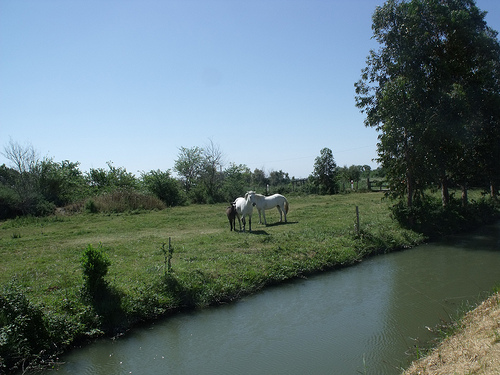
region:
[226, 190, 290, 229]
three horses standing near each other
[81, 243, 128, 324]
a tall bush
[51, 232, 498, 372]
a small stream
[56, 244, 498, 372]
the water is calm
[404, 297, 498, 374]
dead grass by the water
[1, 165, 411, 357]
the field is green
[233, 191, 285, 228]
two white horse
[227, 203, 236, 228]
baby horse is brown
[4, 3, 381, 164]
clear blue skies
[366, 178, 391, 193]
fence gate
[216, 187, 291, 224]
these are the horses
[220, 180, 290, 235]
the horse are standing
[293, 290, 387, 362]
this is the water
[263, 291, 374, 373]
the water is calm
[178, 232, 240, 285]
these are the grass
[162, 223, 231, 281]
the grass are green in color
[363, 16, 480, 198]
this is a tree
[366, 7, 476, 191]
the tree is tall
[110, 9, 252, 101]
this is the sky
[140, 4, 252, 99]
the sky is clear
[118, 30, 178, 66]
this is the sky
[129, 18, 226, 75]
the sky is blue in color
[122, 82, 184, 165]
the sky has clouds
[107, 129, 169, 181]
the clouds are white in color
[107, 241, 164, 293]
this is the grass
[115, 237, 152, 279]
the grass is green in color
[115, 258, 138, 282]
the grass is short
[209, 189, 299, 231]
these are two horses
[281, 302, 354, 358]
this is the water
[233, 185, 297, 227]
the horses are white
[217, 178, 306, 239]
the horses are white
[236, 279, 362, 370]
the water is murky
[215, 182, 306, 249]
two horses arein thefield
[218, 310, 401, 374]
the watr is ina stream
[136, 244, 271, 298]
plants are next to the stream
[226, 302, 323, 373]
the water is bklue in colo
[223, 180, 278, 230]
two horse and a yoyng one are in the picture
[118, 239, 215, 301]
the plants are green in color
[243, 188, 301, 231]
the horses are white in color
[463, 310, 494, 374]
the grass is dried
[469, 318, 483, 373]
the grass is brown incolor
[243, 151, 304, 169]
the sky is clear blue incolor